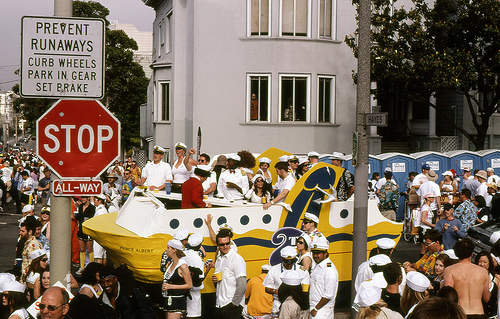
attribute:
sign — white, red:
[43, 95, 112, 169]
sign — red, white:
[49, 172, 103, 201]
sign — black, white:
[22, 13, 109, 102]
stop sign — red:
[32, 93, 129, 199]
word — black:
[29, 20, 83, 91]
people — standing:
[148, 229, 494, 312]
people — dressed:
[252, 174, 369, 210]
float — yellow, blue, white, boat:
[100, 169, 418, 277]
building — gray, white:
[147, 5, 399, 163]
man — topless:
[445, 240, 493, 314]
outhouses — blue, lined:
[362, 148, 498, 177]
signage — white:
[359, 111, 398, 131]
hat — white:
[153, 145, 177, 155]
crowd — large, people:
[339, 178, 499, 294]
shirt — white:
[311, 266, 339, 306]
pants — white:
[310, 303, 350, 317]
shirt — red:
[178, 176, 203, 209]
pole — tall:
[349, 22, 374, 316]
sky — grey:
[12, 5, 56, 48]